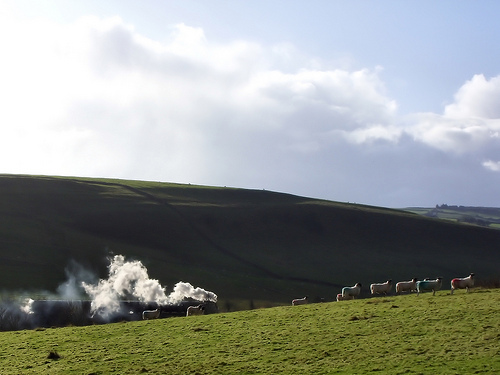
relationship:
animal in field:
[291, 296, 308, 306] [2, 174, 499, 371]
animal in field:
[140, 306, 161, 321] [236, 303, 401, 370]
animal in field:
[415, 277, 443, 296] [16, 230, 488, 373]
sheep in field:
[266, 274, 362, 346] [279, 286, 431, 371]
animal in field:
[291, 296, 308, 306] [4, 285, 496, 367]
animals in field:
[341, 281, 363, 299] [4, 285, 496, 367]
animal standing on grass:
[415, 277, 443, 296] [4, 283, 496, 371]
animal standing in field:
[287, 296, 308, 311] [126, 317, 493, 367]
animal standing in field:
[137, 299, 163, 323] [2, 331, 497, 373]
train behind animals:
[2, 303, 214, 331] [337, 271, 469, 300]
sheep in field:
[451, 275, 477, 298] [4, 285, 496, 367]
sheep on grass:
[183, 300, 203, 313] [343, 304, 467, 366]